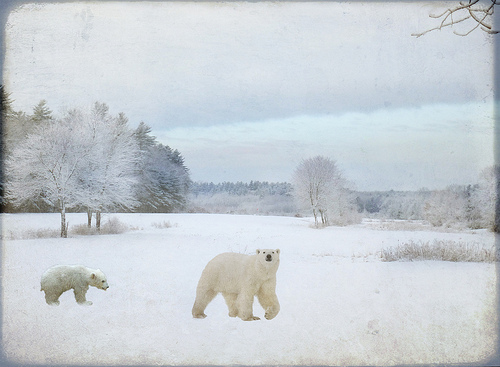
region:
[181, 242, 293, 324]
polar bear on the snow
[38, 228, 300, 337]
two white polar bears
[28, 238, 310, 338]
a baby polar bear behind an adult one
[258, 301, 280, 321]
paw is lifted up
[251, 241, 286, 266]
head is turned to the side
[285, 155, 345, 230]
branches on the tree are white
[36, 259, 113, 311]
side profile of the bear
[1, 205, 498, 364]
white snow on the ground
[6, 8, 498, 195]
thick clouds in the sky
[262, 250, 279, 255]
two small black eyes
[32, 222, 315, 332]
two bears on the snow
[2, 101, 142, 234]
the trees are white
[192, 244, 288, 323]
large white polar bear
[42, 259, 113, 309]
small white polar bear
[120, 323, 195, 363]
snow on the ground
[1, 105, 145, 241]
trees on the ground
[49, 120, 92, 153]
snow on the trees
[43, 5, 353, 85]
clouds in the sky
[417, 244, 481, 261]
grass on the ground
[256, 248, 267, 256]
the bear's right eye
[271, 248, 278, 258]
the bear's left eye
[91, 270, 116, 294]
head of smaller bear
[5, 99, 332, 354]
parent and child polar bears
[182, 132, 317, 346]
a polar bear walking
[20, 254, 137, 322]
a young polar bear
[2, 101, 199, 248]
trees frozen with ice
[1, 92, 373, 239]
trees whose branches are frozen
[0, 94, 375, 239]
trees whose branches are frosted over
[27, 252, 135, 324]
a sad looking young bear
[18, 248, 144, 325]
a tired looking young bear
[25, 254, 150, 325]
a tired looking polar bear cub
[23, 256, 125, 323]
a white polar bear cub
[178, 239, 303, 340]
polar bear in the snow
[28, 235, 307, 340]
small and big polar bear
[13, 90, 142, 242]
tree covered with snow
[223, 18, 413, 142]
sky with clouds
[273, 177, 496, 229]
lot of trees in the snow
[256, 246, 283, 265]
head of the polar bear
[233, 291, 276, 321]
legs of the polar bear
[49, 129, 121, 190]
tree with branches covered with snow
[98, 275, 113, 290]
eye, nose and mouth of the polar bear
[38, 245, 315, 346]
bears are standing in the snow